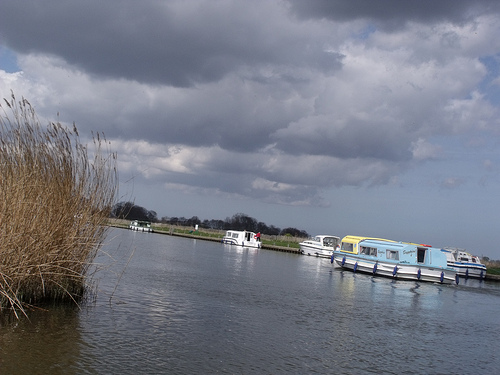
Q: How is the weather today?
A: It is stormy.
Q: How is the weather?
A: It is stormy.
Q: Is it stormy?
A: Yes, it is stormy.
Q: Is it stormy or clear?
A: It is stormy.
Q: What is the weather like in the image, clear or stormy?
A: It is stormy.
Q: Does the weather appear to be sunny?
A: No, it is stormy.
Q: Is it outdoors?
A: Yes, it is outdoors.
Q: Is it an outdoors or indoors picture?
A: It is outdoors.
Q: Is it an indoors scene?
A: No, it is outdoors.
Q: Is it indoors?
A: No, it is outdoors.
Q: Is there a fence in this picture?
A: No, there are no fences.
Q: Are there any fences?
A: No, there are no fences.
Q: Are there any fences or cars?
A: No, there are no fences or cars.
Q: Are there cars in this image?
A: No, there are no cars.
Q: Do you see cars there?
A: No, there are no cars.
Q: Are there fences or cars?
A: No, there are no cars or fences.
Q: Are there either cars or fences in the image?
A: No, there are no cars or fences.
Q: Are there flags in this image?
A: No, there are no flags.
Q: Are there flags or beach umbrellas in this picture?
A: No, there are no flags or beach umbrellas.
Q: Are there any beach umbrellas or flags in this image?
A: No, there are no flags or beach umbrellas.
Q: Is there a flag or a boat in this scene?
A: Yes, there is a boat.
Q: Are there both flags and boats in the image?
A: No, there is a boat but no flags.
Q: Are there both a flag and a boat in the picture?
A: No, there is a boat but no flags.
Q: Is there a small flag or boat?
A: Yes, there is a small boat.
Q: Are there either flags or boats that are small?
A: Yes, the boat is small.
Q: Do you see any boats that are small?
A: Yes, there is a small boat.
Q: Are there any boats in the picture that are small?
A: Yes, there is a boat that is small.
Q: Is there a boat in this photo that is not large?
A: Yes, there is a small boat.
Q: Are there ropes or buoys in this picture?
A: No, there are no ropes or buoys.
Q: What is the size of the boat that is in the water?
A: The boat is small.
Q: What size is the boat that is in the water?
A: The boat is small.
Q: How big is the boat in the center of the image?
A: The boat is small.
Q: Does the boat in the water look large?
A: No, the boat is small.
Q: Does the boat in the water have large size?
A: No, the boat is small.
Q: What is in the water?
A: The boat is in the water.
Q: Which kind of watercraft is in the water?
A: The watercraft is a boat.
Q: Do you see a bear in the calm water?
A: No, there is a boat in the water.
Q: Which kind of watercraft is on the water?
A: The watercraft is a boat.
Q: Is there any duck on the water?
A: No, there is a boat on the water.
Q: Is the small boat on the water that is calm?
A: Yes, the boat is on the water.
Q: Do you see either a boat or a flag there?
A: Yes, there is a boat.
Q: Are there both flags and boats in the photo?
A: No, there is a boat but no flags.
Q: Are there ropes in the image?
A: No, there are no ropes.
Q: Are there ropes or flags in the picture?
A: No, there are no ropes or flags.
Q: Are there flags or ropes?
A: No, there are no ropes or flags.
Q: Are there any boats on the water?
A: Yes, there is a boat on the water.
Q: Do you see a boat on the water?
A: Yes, there is a boat on the water.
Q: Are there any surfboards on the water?
A: No, there is a boat on the water.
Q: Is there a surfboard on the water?
A: No, there is a boat on the water.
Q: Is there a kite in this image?
A: No, there are no kites.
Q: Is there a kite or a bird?
A: No, there are no kites or birds.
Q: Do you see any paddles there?
A: No, there are no paddles.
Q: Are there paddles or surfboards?
A: No, there are no paddles or surfboards.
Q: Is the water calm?
A: Yes, the water is calm.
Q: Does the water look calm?
A: Yes, the water is calm.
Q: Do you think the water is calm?
A: Yes, the water is calm.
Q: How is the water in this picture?
A: The water is calm.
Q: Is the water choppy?
A: No, the water is calm.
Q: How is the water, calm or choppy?
A: The water is calm.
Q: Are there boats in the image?
A: Yes, there is a boat.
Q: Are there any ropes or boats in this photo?
A: Yes, there is a boat.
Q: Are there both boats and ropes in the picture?
A: No, there is a boat but no ropes.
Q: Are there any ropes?
A: No, there are no ropes.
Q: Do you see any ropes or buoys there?
A: No, there are no ropes or buoys.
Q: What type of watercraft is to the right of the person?
A: The watercraft is a boat.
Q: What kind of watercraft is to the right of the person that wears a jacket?
A: The watercraft is a boat.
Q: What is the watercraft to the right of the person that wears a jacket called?
A: The watercraft is a boat.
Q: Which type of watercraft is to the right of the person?
A: The watercraft is a boat.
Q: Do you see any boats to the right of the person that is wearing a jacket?
A: Yes, there is a boat to the right of the person.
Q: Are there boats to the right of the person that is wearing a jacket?
A: Yes, there is a boat to the right of the person.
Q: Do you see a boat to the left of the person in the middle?
A: No, the boat is to the right of the person.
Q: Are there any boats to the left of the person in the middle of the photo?
A: No, the boat is to the right of the person.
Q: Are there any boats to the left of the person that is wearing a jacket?
A: No, the boat is to the right of the person.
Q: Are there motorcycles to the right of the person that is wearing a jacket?
A: No, there is a boat to the right of the person.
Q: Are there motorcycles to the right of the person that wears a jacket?
A: No, there is a boat to the right of the person.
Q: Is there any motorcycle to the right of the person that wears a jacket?
A: No, there is a boat to the right of the person.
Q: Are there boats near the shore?
A: Yes, there is a boat near the shore.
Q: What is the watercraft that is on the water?
A: The watercraft is a boat.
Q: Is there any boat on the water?
A: Yes, there is a boat on the water.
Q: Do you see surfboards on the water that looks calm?
A: No, there is a boat on the water.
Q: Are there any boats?
A: Yes, there is a boat.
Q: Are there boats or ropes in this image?
A: Yes, there is a boat.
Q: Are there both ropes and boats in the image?
A: No, there is a boat but no ropes.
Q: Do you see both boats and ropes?
A: No, there is a boat but no ropes.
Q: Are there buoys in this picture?
A: No, there are no buoys.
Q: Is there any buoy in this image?
A: No, there are no buoys.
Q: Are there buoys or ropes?
A: No, there are no buoys or ropes.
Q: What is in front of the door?
A: The boat is in front of the door.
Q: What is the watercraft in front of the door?
A: The watercraft is a boat.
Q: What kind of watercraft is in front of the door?
A: The watercraft is a boat.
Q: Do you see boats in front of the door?
A: Yes, there is a boat in front of the door.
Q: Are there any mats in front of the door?
A: No, there is a boat in front of the door.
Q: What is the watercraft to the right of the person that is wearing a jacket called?
A: The watercraft is a boat.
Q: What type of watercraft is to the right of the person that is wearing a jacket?
A: The watercraft is a boat.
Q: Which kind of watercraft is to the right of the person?
A: The watercraft is a boat.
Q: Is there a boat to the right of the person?
A: Yes, there is a boat to the right of the person.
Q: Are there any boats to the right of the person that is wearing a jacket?
A: Yes, there is a boat to the right of the person.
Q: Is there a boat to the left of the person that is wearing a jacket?
A: No, the boat is to the right of the person.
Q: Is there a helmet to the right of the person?
A: No, there is a boat to the right of the person.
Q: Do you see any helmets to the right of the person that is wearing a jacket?
A: No, there is a boat to the right of the person.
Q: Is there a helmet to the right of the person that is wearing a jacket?
A: No, there is a boat to the right of the person.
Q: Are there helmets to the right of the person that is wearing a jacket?
A: No, there is a boat to the right of the person.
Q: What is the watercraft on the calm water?
A: The watercraft is a boat.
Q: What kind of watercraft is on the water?
A: The watercraft is a boat.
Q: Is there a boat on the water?
A: Yes, there is a boat on the water.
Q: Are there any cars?
A: No, there are no cars.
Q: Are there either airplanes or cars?
A: No, there are no cars or airplanes.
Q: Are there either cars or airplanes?
A: No, there are no cars or airplanes.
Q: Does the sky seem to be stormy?
A: Yes, the sky is stormy.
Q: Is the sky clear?
A: No, the sky is stormy.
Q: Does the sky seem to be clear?
A: No, the sky is stormy.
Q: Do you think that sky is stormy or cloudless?
A: The sky is stormy.